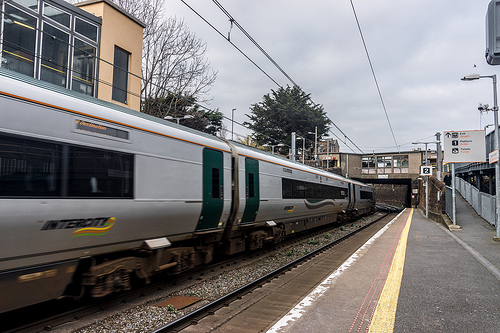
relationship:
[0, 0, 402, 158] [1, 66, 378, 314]
wires above train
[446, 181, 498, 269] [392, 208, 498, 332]
ramp to platform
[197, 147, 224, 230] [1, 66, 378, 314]
door on train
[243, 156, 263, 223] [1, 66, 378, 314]
door on train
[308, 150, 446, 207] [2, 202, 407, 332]
bridge over rails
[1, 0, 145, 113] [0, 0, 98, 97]
building has windows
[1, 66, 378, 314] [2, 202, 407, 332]
train on rails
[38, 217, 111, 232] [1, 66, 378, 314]
word on train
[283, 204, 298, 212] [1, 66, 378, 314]
word on train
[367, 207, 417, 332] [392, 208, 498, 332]
line on platform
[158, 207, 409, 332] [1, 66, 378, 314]
track by train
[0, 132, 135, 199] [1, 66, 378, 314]
window on train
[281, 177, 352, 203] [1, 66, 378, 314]
window on train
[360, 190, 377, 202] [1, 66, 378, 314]
window on train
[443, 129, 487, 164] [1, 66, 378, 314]
sign by train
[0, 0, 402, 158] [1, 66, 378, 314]
wires over train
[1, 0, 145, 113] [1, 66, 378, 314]
building by train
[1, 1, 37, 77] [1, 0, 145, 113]
window on building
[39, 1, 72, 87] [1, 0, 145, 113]
window on building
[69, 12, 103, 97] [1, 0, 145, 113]
window on building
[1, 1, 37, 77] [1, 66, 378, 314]
window overlooks train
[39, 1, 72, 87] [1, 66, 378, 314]
window overlooks train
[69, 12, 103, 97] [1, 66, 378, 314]
window overlooks train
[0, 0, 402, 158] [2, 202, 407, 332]
wires over rails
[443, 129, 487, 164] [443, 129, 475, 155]
sign gives directions